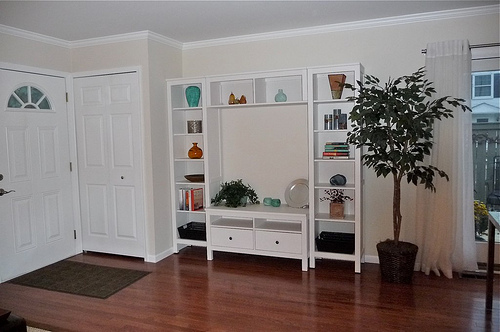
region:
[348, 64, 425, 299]
tree in wicker pot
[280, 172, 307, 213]
silver plate on shelf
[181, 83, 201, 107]
green vase on shelf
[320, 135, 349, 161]
stack of books on shelf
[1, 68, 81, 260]
white door with small window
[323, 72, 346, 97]
brown vase on shelf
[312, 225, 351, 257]
black wicker basket on shelf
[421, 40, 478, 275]
white sheer curtains on silver rod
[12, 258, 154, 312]
small rug at front door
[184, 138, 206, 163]
brown glass jar on shelf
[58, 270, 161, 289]
dark brown front door rug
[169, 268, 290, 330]
cherry colored hardwood floors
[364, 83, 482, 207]
green plant with brown vase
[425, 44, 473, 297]
white long sheer curtain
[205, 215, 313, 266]
two white cabinets with black knobs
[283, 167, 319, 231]
silver metallic plate on ledge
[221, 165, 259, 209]
green plant with green pot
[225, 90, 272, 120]
three pears on top shelf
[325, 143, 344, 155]
a stack of books on shelf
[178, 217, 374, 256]
two black baskets in shelves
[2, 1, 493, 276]
White walls.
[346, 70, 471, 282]
An indoor tree.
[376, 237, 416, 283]
A dark woven flowerpot.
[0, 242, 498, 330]
Hardwood floors.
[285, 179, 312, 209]
A round white plate.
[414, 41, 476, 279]
Long white curtains.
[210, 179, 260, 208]
A green houseplant.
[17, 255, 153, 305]
A dark colored rug.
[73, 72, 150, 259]
A white door.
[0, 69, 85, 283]
A white front door with windows at the top.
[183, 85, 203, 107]
A green glass vase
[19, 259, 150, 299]
A brown doormat at entrance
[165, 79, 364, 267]
White decorative shelves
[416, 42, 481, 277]
Thin white curtains on rod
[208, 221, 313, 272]
small white drawers with black handles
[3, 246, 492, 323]
dark glossy hardwood flooring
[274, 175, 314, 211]
A reflective metal plate on a stand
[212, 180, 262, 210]
A small flowerless houseplant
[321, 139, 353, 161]
a few stacked books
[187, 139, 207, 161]
A tan clay pot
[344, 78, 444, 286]
green plant in the room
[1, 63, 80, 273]
white front door with window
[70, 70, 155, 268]
white closet door with no door knob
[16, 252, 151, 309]
brown mat near front door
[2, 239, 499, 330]
brown hardwood floor in room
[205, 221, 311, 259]
two white drawers in display stand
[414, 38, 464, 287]
white sheer curtain on window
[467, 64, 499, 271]
large window on side of room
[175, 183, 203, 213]
group of books on shelf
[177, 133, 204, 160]
red vase on shelf